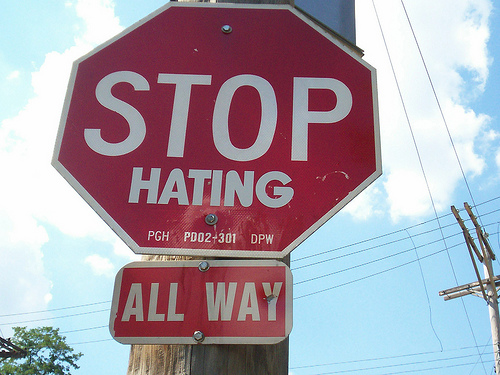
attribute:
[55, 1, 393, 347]
sign — red, white, stop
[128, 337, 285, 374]
pole — wooden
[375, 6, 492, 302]
lines — hanging, black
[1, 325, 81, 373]
tree — showing, green, dark, leafy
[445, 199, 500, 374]
post — electrical, white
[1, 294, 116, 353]
wires — hanging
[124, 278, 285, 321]
all way — small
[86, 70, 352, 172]
stop — white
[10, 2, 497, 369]
sky — blue, bright, clear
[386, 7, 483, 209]
clouds — white, bright, fluffy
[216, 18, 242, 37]
bolt — silver, attached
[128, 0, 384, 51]
border — white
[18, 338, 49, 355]
leaves — green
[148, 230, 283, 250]
number — serial